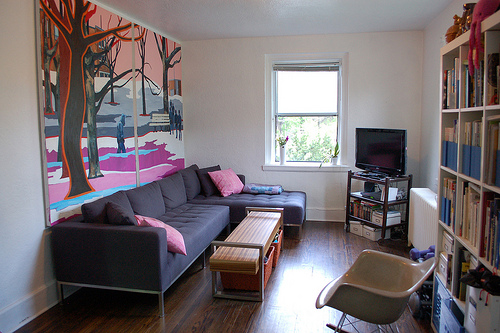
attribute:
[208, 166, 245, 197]
pillow — pink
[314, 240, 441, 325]
chair — white, gray, plastic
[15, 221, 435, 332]
floor — brown, wood, hard wood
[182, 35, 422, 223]
wall — painted, white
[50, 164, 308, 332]
sofa — black, wrap around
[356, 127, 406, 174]
tv — black, flat screen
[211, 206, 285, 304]
table — wooden, wood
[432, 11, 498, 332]
bookcase — large, full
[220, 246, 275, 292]
containers — orange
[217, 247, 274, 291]
basket — orange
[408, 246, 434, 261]
weights — purple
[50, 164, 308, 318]
couch — gray